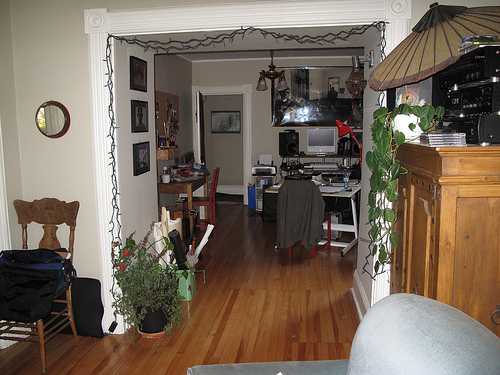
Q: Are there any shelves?
A: No, there are no shelves.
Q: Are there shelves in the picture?
A: No, there are no shelves.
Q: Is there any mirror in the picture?
A: Yes, there is a mirror.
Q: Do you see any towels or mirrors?
A: Yes, there is a mirror.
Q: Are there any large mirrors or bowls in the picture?
A: Yes, there is a large mirror.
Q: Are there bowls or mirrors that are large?
A: Yes, the mirror is large.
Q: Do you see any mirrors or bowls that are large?
A: Yes, the mirror is large.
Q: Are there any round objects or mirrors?
A: Yes, there is a round mirror.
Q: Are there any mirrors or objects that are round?
A: Yes, the mirror is round.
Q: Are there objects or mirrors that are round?
A: Yes, the mirror is round.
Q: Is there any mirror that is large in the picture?
A: Yes, there is a large mirror.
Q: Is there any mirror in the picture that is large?
A: Yes, there is a mirror that is large.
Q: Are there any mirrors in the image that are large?
A: Yes, there is a mirror that is large.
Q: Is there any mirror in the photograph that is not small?
A: Yes, there is a large mirror.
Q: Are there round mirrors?
A: Yes, there is a round mirror.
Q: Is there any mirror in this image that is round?
A: Yes, there is a mirror that is round.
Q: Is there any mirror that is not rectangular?
A: Yes, there is a round mirror.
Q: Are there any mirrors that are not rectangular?
A: Yes, there is a round mirror.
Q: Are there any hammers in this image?
A: No, there are no hammers.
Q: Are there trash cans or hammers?
A: No, there are no hammers or trash cans.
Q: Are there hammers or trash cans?
A: No, there are no hammers or trash cans.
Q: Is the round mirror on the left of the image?
A: Yes, the mirror is on the left of the image.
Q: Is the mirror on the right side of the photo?
A: No, the mirror is on the left of the image.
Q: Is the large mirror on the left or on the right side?
A: The mirror is on the left of the image.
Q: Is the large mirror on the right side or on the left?
A: The mirror is on the left of the image.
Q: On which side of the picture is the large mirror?
A: The mirror is on the left of the image.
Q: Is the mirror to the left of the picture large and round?
A: Yes, the mirror is large and round.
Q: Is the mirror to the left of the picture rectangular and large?
A: No, the mirror is large but round.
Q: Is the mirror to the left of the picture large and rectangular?
A: No, the mirror is large but round.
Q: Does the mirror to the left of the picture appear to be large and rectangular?
A: No, the mirror is large but round.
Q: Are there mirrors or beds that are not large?
A: No, there is a mirror but it is large.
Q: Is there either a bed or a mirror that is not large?
A: No, there is a mirror but it is large.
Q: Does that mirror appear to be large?
A: Yes, the mirror is large.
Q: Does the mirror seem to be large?
A: Yes, the mirror is large.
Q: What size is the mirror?
A: The mirror is large.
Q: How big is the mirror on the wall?
A: The mirror is large.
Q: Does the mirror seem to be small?
A: No, the mirror is large.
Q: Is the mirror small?
A: No, the mirror is large.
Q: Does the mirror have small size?
A: No, the mirror is large.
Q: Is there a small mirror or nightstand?
A: No, there is a mirror but it is large.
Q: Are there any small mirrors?
A: No, there is a mirror but it is large.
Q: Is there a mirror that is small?
A: No, there is a mirror but it is large.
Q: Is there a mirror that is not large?
A: No, there is a mirror but it is large.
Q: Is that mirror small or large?
A: The mirror is large.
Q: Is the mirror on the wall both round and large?
A: Yes, the mirror is round and large.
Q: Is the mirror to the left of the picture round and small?
A: No, the mirror is round but large.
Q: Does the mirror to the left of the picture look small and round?
A: No, the mirror is round but large.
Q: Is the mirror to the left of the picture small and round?
A: No, the mirror is round but large.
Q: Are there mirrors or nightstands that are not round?
A: No, there is a mirror but it is round.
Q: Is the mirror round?
A: Yes, the mirror is round.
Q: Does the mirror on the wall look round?
A: Yes, the mirror is round.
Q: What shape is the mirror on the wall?
A: The mirror is round.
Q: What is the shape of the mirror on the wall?
A: The mirror is round.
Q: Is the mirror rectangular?
A: No, the mirror is round.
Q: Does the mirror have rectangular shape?
A: No, the mirror is round.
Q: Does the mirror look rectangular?
A: No, the mirror is round.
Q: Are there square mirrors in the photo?
A: No, there is a mirror but it is round.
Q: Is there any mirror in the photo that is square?
A: No, there is a mirror but it is round.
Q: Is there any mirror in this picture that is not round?
A: No, there is a mirror but it is round.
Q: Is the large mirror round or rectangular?
A: The mirror is round.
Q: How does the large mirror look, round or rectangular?
A: The mirror is round.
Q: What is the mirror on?
A: The mirror is on the wall.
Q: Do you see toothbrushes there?
A: No, there are no toothbrushes.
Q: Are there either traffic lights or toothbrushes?
A: No, there are no toothbrushes or traffic lights.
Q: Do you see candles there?
A: No, there are no candles.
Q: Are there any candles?
A: No, there are no candles.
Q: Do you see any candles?
A: No, there are no candles.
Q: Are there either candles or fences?
A: No, there are no candles or fences.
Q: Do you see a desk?
A: Yes, there is a desk.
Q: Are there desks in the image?
A: Yes, there is a desk.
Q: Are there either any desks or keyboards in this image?
A: Yes, there is a desk.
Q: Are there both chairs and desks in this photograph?
A: Yes, there are both a desk and a chair.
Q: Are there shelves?
A: No, there are no shelves.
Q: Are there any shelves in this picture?
A: No, there are no shelves.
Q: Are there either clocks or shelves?
A: No, there are no shelves or clocks.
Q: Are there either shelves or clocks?
A: No, there are no shelves or clocks.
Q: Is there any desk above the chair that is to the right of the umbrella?
A: Yes, there is a desk above the chair.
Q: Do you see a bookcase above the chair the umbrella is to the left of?
A: No, there is a desk above the chair.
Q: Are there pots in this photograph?
A: Yes, there is a pot.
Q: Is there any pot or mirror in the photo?
A: Yes, there is a pot.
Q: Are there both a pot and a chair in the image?
A: Yes, there are both a pot and a chair.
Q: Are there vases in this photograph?
A: No, there are no vases.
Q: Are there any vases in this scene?
A: No, there are no vases.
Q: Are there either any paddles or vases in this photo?
A: No, there are no vases or paddles.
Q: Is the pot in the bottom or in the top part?
A: The pot is in the bottom of the image.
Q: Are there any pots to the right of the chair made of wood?
A: Yes, there is a pot to the right of the chair.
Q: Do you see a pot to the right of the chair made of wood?
A: Yes, there is a pot to the right of the chair.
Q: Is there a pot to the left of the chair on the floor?
A: No, the pot is to the right of the chair.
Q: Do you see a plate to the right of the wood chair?
A: No, there is a pot to the right of the chair.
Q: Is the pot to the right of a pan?
A: No, the pot is to the right of the chair.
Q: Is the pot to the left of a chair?
A: No, the pot is to the right of a chair.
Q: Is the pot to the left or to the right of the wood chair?
A: The pot is to the right of the chair.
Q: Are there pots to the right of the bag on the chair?
A: Yes, there is a pot to the right of the bag.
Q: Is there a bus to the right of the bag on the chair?
A: No, there is a pot to the right of the bag.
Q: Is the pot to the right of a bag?
A: Yes, the pot is to the right of a bag.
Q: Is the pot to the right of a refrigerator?
A: No, the pot is to the right of a bag.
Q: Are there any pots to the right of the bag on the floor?
A: Yes, there is a pot to the right of the bag.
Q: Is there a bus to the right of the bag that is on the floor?
A: No, there is a pot to the right of the bag.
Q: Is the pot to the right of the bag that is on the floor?
A: Yes, the pot is to the right of the bag.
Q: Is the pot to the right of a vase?
A: No, the pot is to the right of the bag.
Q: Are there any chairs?
A: Yes, there is a chair.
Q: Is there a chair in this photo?
A: Yes, there is a chair.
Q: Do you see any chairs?
A: Yes, there is a chair.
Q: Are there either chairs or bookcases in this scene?
A: Yes, there is a chair.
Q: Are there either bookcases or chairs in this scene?
A: Yes, there is a chair.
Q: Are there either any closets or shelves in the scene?
A: No, there are no shelves or closets.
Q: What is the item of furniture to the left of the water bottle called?
A: The piece of furniture is a chair.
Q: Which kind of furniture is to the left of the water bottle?
A: The piece of furniture is a chair.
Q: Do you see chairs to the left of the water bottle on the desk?
A: Yes, there is a chair to the left of the water bottle.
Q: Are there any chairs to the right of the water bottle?
A: No, the chair is to the left of the water bottle.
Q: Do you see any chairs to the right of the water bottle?
A: No, the chair is to the left of the water bottle.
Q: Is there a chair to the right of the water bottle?
A: No, the chair is to the left of the water bottle.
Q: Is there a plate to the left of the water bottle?
A: No, there is a chair to the left of the water bottle.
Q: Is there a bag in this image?
A: Yes, there is a bag.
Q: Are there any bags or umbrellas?
A: Yes, there is a bag.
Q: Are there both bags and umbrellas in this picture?
A: Yes, there are both a bag and an umbrella.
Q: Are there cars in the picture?
A: No, there are no cars.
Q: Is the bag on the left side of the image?
A: Yes, the bag is on the left of the image.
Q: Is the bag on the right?
A: No, the bag is on the left of the image.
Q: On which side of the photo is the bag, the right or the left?
A: The bag is on the left of the image.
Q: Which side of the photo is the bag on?
A: The bag is on the left of the image.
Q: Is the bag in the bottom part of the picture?
A: Yes, the bag is in the bottom of the image.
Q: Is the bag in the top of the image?
A: No, the bag is in the bottom of the image.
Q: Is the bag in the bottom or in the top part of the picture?
A: The bag is in the bottom of the image.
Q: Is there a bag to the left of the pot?
A: Yes, there is a bag to the left of the pot.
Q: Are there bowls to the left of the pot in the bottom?
A: No, there is a bag to the left of the pot.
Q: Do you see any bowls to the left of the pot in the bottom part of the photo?
A: No, there is a bag to the left of the pot.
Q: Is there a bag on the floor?
A: Yes, there is a bag on the floor.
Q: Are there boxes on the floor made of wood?
A: No, there is a bag on the floor.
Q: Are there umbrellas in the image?
A: Yes, there is an umbrella.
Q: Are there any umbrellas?
A: Yes, there is an umbrella.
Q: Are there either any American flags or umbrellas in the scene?
A: Yes, there is an umbrella.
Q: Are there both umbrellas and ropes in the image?
A: No, there is an umbrella but no ropes.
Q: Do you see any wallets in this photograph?
A: No, there are no wallets.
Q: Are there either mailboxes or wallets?
A: No, there are no wallets or mailboxes.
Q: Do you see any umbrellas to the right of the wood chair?
A: Yes, there is an umbrella to the right of the chair.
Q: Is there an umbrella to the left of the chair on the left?
A: No, the umbrella is to the right of the chair.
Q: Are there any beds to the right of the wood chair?
A: No, there is an umbrella to the right of the chair.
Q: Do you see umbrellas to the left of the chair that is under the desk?
A: Yes, there is an umbrella to the left of the chair.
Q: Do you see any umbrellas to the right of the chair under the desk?
A: No, the umbrella is to the left of the chair.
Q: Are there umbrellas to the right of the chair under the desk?
A: No, the umbrella is to the left of the chair.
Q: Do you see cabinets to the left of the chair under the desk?
A: No, there is an umbrella to the left of the chair.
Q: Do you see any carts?
A: No, there are no carts.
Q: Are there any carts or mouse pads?
A: No, there are no carts or mouse pads.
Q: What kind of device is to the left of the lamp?
A: The device is a monitor.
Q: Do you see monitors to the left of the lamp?
A: Yes, there is a monitor to the left of the lamp.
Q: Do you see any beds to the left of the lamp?
A: No, there is a monitor to the left of the lamp.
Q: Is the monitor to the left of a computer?
A: No, the monitor is to the left of the lamp.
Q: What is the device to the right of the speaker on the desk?
A: The device is a monitor.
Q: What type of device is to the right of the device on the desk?
A: The device is a monitor.